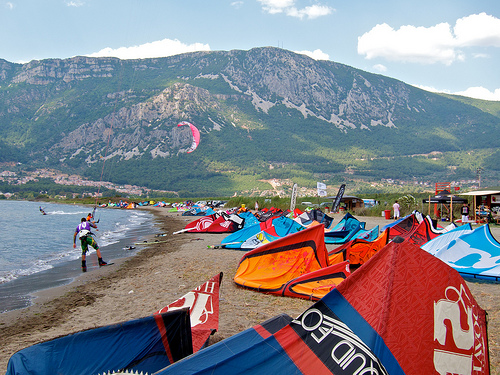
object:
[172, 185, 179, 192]
tree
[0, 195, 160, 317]
ocean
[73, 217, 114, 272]
man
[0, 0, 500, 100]
sky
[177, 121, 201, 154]
kite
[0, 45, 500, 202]
mountain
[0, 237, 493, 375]
kites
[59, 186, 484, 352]
beach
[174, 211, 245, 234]
kite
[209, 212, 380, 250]
kite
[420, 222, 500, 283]
kite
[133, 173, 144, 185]
tree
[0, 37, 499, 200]
distance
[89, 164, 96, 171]
tree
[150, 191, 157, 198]
tree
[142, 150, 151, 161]
tree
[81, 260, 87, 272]
footstep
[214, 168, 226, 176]
tree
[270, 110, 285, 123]
tree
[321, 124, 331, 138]
tree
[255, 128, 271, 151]
tree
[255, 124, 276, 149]
tree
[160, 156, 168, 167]
tree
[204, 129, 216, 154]
tree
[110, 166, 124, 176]
tree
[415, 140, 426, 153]
tree